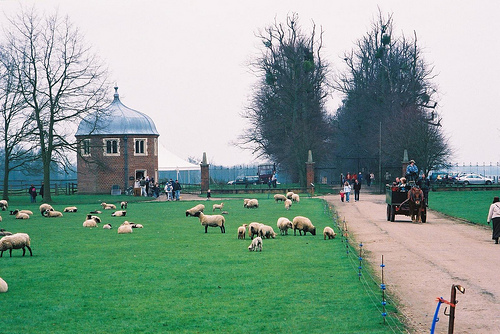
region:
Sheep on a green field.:
[5, 192, 337, 292]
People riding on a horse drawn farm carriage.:
[380, 155, 435, 225]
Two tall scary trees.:
[237, 5, 443, 185]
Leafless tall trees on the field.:
[0, 0, 105, 200]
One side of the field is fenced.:
[310, 190, 415, 327]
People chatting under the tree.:
[25, 175, 48, 206]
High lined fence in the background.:
[161, 162, 258, 186]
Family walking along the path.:
[335, 176, 363, 201]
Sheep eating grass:
[232, 216, 339, 259]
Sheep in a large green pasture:
[19, 200, 329, 306]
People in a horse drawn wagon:
[380, 156, 444, 223]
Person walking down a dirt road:
[479, 194, 498, 247]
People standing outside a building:
[132, 166, 185, 200]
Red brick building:
[75, 134, 160, 195]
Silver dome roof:
[66, 85, 161, 135]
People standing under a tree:
[25, 180, 47, 204]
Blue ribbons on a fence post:
[379, 256, 389, 324]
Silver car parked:
[454, 172, 497, 187]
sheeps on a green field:
[0, 187, 344, 301]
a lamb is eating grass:
[243, 231, 268, 255]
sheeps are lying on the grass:
[79, 207, 146, 239]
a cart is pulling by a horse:
[373, 170, 435, 246]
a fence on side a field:
[337, 221, 458, 322]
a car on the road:
[447, 162, 497, 190]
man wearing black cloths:
[349, 174, 363, 201]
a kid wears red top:
[336, 185, 347, 200]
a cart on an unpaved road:
[351, 164, 482, 276]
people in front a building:
[119, 136, 183, 199]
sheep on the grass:
[196, 212, 233, 237]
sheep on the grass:
[239, 235, 269, 267]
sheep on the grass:
[321, 216, 341, 247]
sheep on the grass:
[116, 219, 138, 242]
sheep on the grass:
[76, 216, 98, 231]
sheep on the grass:
[124, 215, 143, 234]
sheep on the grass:
[1, 241, 38, 259]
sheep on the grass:
[75, 212, 103, 227]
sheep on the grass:
[105, 204, 130, 218]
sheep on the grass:
[179, 198, 201, 215]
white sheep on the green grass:
[193, 208, 224, 229]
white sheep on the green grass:
[285, 213, 320, 238]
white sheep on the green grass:
[240, 195, 261, 208]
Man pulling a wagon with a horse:
[371, 142, 452, 260]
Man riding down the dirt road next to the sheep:
[378, 145, 440, 250]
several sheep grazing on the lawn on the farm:
[4, 203, 337, 329]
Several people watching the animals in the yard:
[116, 161, 224, 225]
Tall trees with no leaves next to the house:
[253, 8, 466, 213]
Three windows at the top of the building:
[71, 125, 178, 170]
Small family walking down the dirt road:
[338, 166, 383, 233]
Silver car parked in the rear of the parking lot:
[445, 165, 496, 195]